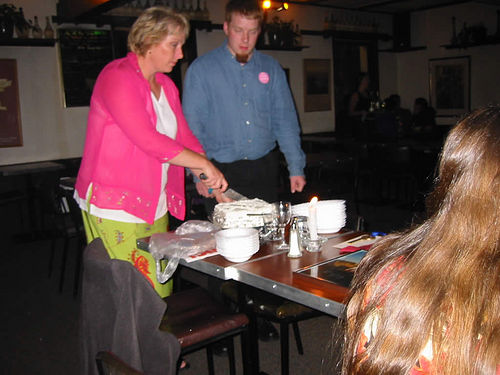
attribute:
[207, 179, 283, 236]
cake — fancy, being cut, table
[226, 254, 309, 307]
table — red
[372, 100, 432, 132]
jacket — gray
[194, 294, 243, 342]
chair — red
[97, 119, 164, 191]
jacket — pink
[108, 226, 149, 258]
pant — floral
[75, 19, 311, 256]
people — enjoying, having, in living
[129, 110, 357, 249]
person — using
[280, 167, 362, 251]
plate — stacked, white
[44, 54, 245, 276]
woman — cutting, middle aged, cut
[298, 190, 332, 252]
candle — white, lit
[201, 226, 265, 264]
bowl — stack, white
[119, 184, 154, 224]
button — pink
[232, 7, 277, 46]
head — man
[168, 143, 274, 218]
hand — grasping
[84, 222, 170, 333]
coat — covering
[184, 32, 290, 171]
man — young, seeve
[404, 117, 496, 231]
waitress — carrying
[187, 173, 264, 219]
knife — wood, black, short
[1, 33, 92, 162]
wall — painting, white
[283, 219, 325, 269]
salt — shaker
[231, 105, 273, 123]
shirt — blue, go-tee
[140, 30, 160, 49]
hair — girl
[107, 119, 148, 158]
shirt — pink